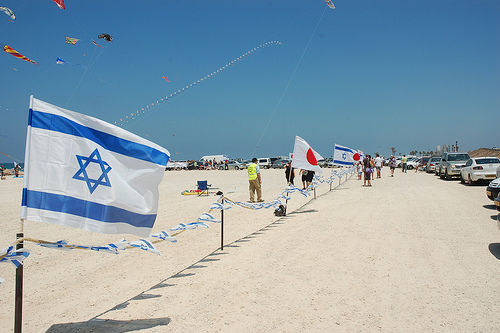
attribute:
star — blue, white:
[71, 146, 114, 195]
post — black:
[215, 189, 229, 243]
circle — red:
[306, 149, 316, 169]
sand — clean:
[6, 173, 496, 329]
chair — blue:
[197, 176, 211, 194]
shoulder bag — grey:
[365, 158, 373, 173]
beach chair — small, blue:
[183, 180, 213, 192]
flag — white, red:
[281, 135, 323, 205]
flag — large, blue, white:
[18, 94, 168, 239]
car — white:
[462, 157, 498, 186]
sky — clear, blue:
[4, 1, 497, 162]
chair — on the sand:
[194, 177, 214, 196]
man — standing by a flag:
[245, 152, 265, 203]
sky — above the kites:
[349, 32, 443, 125]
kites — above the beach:
[0, 4, 120, 83]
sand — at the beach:
[45, 244, 375, 330]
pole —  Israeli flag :
[7, 227, 29, 327]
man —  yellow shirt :
[244, 159, 271, 205]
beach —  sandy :
[322, 198, 448, 330]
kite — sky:
[45, 14, 125, 64]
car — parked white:
[161, 146, 198, 172]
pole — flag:
[24, 86, 162, 327]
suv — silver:
[168, 162, 195, 176]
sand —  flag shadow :
[226, 290, 421, 330]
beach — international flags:
[10, 82, 360, 267]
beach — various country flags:
[5, 91, 366, 330]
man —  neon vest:
[244, 153, 264, 204]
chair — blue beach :
[184, 173, 233, 199]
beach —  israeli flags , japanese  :
[191, 268, 431, 331]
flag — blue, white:
[13, 91, 173, 243]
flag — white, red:
[288, 134, 327, 180]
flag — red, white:
[288, 132, 326, 176]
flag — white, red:
[288, 128, 327, 178]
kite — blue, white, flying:
[52, 52, 66, 69]